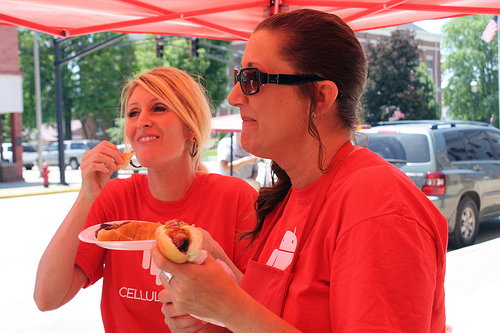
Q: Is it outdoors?
A: Yes, it is outdoors.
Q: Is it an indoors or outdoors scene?
A: It is outdoors.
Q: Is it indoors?
A: No, it is outdoors.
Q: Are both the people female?
A: Yes, all the people are female.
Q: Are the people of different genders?
A: No, all the people are female.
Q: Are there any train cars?
A: No, there are no train cars.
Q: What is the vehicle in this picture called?
A: The vehicle is a car.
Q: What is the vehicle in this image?
A: The vehicle is a car.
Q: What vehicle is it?
A: The vehicle is a car.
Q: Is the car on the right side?
A: Yes, the car is on the right of the image.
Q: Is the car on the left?
A: No, the car is on the right of the image.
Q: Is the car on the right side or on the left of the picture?
A: The car is on the right of the image.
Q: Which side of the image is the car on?
A: The car is on the right of the image.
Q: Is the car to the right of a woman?
A: Yes, the car is to the right of a woman.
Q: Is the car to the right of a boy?
A: No, the car is to the right of a woman.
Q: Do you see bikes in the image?
A: No, there are no bikes.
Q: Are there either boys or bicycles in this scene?
A: No, there are no bicycles or boys.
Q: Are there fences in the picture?
A: No, there are no fences.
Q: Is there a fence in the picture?
A: No, there are no fences.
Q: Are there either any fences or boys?
A: No, there are no fences or boys.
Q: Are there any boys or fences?
A: No, there are no fences or boys.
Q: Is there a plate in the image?
A: Yes, there is a plate.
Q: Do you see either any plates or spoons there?
A: Yes, there is a plate.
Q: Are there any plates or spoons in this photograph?
A: Yes, there is a plate.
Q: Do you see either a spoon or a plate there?
A: Yes, there is a plate.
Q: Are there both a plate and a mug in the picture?
A: No, there is a plate but no mugs.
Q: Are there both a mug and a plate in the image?
A: No, there is a plate but no mugs.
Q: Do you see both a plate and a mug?
A: No, there is a plate but no mugs.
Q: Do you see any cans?
A: No, there are no cans.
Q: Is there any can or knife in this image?
A: No, there are no cans or knives.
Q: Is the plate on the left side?
A: Yes, the plate is on the left of the image.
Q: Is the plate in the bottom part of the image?
A: Yes, the plate is in the bottom of the image.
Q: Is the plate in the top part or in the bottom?
A: The plate is in the bottom of the image.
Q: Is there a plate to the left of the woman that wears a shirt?
A: Yes, there is a plate to the left of the woman.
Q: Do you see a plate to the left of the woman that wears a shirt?
A: Yes, there is a plate to the left of the woman.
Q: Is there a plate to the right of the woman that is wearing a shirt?
A: No, the plate is to the left of the woman.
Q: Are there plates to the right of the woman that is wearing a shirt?
A: No, the plate is to the left of the woman.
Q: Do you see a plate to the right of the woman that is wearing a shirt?
A: No, the plate is to the left of the woman.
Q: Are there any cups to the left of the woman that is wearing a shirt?
A: No, there is a plate to the left of the woman.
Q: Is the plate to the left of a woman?
A: Yes, the plate is to the left of a woman.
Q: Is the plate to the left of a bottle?
A: No, the plate is to the left of a woman.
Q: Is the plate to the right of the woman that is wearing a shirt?
A: No, the plate is to the left of the woman.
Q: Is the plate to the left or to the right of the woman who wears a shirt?
A: The plate is to the left of the woman.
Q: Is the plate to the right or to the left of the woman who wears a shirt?
A: The plate is to the left of the woman.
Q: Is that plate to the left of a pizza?
A: No, the plate is to the left of a hot dog.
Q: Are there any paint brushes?
A: No, there are no paint brushes.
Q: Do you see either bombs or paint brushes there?
A: No, there are no paint brushes or bombs.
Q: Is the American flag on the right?
A: Yes, the American flag is on the right of the image.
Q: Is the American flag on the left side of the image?
A: No, the American flag is on the right of the image.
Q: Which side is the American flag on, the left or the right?
A: The American flag is on the right of the image.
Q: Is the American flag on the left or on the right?
A: The American flag is on the right of the image.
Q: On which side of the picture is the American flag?
A: The American flag is on the right of the image.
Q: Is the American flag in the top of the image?
A: Yes, the American flag is in the top of the image.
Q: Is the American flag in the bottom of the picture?
A: No, the American flag is in the top of the image.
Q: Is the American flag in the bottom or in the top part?
A: The American flag is in the top of the image.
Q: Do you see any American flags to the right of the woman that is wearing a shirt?
A: Yes, there is an American flag to the right of the woman.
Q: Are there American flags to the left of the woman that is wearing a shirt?
A: No, the American flag is to the right of the woman.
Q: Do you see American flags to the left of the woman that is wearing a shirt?
A: No, the American flag is to the right of the woman.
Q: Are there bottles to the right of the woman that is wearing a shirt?
A: No, there is an American flag to the right of the woman.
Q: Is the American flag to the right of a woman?
A: Yes, the American flag is to the right of a woman.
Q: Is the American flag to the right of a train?
A: No, the American flag is to the right of a woman.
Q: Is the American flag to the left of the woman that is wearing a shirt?
A: No, the American flag is to the right of the woman.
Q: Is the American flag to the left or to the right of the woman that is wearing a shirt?
A: The American flag is to the right of the woman.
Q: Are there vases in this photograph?
A: No, there are no vases.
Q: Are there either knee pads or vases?
A: No, there are no vases or knee pads.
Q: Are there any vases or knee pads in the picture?
A: No, there are no vases or knee pads.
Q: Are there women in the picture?
A: Yes, there is a woman.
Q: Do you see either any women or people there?
A: Yes, there is a woman.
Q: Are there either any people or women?
A: Yes, there is a woman.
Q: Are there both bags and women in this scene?
A: No, there is a woman but no bags.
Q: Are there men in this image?
A: No, there are no men.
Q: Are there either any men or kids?
A: No, there are no men or kids.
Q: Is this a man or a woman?
A: This is a woman.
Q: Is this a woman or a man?
A: This is a woman.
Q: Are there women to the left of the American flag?
A: Yes, there is a woman to the left of the American flag.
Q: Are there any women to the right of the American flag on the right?
A: No, the woman is to the left of the American flag.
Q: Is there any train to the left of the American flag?
A: No, there is a woman to the left of the American flag.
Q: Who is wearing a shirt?
A: The woman is wearing a shirt.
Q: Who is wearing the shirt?
A: The woman is wearing a shirt.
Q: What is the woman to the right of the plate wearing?
A: The woman is wearing a shirt.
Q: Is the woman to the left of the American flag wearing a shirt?
A: Yes, the woman is wearing a shirt.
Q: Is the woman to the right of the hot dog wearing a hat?
A: No, the woman is wearing a shirt.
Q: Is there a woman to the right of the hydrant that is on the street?
A: Yes, there is a woman to the right of the fire hydrant.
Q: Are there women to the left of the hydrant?
A: No, the woman is to the right of the hydrant.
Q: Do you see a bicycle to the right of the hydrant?
A: No, there is a woman to the right of the hydrant.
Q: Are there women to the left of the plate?
A: No, the woman is to the right of the plate.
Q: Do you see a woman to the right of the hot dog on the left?
A: Yes, there is a woman to the right of the hot dog.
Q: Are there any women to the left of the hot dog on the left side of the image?
A: No, the woman is to the right of the hot dog.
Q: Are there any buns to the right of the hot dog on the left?
A: No, there is a woman to the right of the hot dog.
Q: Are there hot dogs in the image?
A: Yes, there is a hot dog.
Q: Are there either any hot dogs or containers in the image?
A: Yes, there is a hot dog.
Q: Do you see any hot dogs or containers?
A: Yes, there is a hot dog.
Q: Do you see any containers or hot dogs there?
A: Yes, there is a hot dog.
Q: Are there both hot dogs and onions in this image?
A: No, there is a hot dog but no onions.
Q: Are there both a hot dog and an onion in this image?
A: No, there is a hot dog but no onions.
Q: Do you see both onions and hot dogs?
A: No, there is a hot dog but no onions.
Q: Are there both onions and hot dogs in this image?
A: No, there is a hot dog but no onions.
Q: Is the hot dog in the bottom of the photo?
A: Yes, the hot dog is in the bottom of the image.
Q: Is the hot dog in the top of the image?
A: No, the hot dog is in the bottom of the image.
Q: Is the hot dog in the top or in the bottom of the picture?
A: The hot dog is in the bottom of the image.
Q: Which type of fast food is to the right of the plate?
A: The food is a hot dog.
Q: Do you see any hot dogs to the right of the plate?
A: Yes, there is a hot dog to the right of the plate.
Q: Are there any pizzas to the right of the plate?
A: No, there is a hot dog to the right of the plate.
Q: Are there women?
A: Yes, there is a woman.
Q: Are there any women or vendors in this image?
A: Yes, there is a woman.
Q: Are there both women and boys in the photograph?
A: No, there is a woman but no boys.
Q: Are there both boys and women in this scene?
A: No, there is a woman but no boys.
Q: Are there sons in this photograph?
A: No, there are no sons.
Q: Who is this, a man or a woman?
A: This is a woman.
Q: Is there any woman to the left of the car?
A: Yes, there is a woman to the left of the car.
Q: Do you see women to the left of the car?
A: Yes, there is a woman to the left of the car.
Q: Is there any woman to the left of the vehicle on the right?
A: Yes, there is a woman to the left of the car.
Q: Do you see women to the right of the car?
A: No, the woman is to the left of the car.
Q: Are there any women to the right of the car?
A: No, the woman is to the left of the car.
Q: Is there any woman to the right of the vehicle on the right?
A: No, the woman is to the left of the car.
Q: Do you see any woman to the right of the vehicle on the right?
A: No, the woman is to the left of the car.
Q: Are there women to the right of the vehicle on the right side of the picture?
A: No, the woman is to the left of the car.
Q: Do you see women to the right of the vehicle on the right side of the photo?
A: No, the woman is to the left of the car.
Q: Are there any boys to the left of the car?
A: No, there is a woman to the left of the car.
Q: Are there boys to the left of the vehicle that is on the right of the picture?
A: No, there is a woman to the left of the car.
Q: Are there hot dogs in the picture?
A: Yes, there is a hot dog.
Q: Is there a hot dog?
A: Yes, there is a hot dog.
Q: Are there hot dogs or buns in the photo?
A: Yes, there is a hot dog.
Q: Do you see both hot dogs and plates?
A: Yes, there are both a hot dog and a plate.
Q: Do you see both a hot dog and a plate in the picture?
A: Yes, there are both a hot dog and a plate.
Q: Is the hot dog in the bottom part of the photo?
A: Yes, the hot dog is in the bottom of the image.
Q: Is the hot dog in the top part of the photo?
A: No, the hot dog is in the bottom of the image.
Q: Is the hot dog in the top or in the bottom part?
A: The hot dog is in the bottom of the image.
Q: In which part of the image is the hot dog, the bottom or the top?
A: The hot dog is in the bottom of the image.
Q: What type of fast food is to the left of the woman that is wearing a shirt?
A: The food is a hot dog.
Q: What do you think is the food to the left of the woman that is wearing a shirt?
A: The food is a hot dog.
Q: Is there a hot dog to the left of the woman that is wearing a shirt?
A: Yes, there is a hot dog to the left of the woman.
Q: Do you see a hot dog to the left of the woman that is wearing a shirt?
A: Yes, there is a hot dog to the left of the woman.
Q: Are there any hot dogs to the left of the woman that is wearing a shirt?
A: Yes, there is a hot dog to the left of the woman.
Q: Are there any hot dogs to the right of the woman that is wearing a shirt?
A: No, the hot dog is to the left of the woman.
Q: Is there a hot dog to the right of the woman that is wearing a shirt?
A: No, the hot dog is to the left of the woman.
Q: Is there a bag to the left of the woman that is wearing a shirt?
A: No, there is a hot dog to the left of the woman.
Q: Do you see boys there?
A: No, there are no boys.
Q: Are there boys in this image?
A: No, there are no boys.